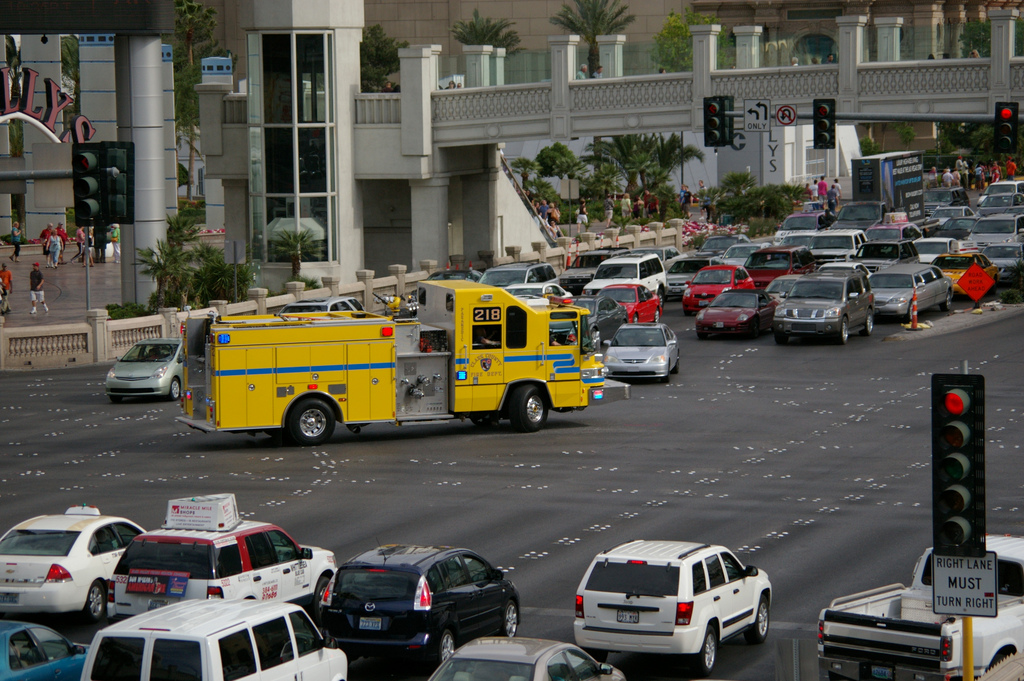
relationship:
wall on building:
[368, 182, 455, 277] [197, 0, 1019, 294]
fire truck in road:
[176, 280, 609, 443] [0, 205, 1024, 681]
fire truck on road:
[176, 280, 609, 443] [0, 205, 1024, 681]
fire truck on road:
[176, 280, 609, 443] [0, 138, 1024, 677]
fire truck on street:
[176, 280, 609, 443] [9, 185, 993, 665]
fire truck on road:
[172, 276, 629, 444] [5, 245, 993, 678]